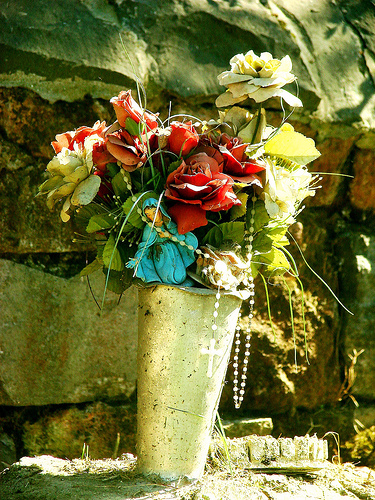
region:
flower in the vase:
[181, 165, 238, 216]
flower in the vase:
[258, 167, 304, 206]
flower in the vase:
[107, 127, 149, 171]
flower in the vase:
[45, 154, 88, 194]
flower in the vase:
[223, 50, 294, 115]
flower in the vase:
[41, 163, 94, 206]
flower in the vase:
[168, 123, 197, 151]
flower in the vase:
[204, 133, 261, 176]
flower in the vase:
[261, 186, 288, 227]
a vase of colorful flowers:
[38, 49, 352, 482]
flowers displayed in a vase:
[38, 39, 356, 471]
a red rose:
[159, 146, 244, 231]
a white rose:
[216, 48, 300, 127]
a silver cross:
[198, 339, 224, 376]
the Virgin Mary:
[123, 194, 198, 288]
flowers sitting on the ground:
[40, 50, 355, 483]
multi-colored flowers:
[46, 49, 358, 478]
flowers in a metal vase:
[40, 42, 356, 478]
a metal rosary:
[113, 116, 259, 410]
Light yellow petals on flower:
[271, 130, 316, 155]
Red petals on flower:
[168, 201, 207, 233]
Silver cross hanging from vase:
[202, 338, 226, 378]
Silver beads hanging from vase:
[233, 326, 248, 406]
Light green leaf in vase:
[86, 212, 112, 231]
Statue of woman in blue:
[131, 197, 199, 285]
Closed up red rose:
[109, 88, 146, 132]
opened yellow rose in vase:
[219, 47, 300, 107]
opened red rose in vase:
[169, 155, 238, 226]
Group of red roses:
[103, 92, 152, 165]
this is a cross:
[161, 293, 234, 376]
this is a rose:
[191, 194, 257, 282]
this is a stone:
[134, 387, 248, 446]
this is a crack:
[54, 238, 97, 284]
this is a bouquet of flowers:
[171, 242, 237, 276]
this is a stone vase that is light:
[128, 358, 222, 427]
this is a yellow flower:
[257, 182, 293, 221]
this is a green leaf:
[100, 213, 118, 322]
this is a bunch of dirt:
[245, 431, 328, 489]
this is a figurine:
[48, 123, 171, 274]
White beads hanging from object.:
[232, 302, 255, 411]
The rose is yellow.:
[214, 44, 304, 112]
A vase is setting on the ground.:
[134, 285, 233, 481]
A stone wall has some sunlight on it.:
[1, 1, 373, 405]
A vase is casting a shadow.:
[0, 280, 240, 498]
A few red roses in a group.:
[50, 87, 264, 230]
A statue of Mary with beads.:
[127, 198, 200, 283]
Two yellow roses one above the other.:
[205, 45, 315, 215]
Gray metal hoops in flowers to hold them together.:
[102, 104, 203, 284]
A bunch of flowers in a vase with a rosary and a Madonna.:
[9, 51, 371, 480]